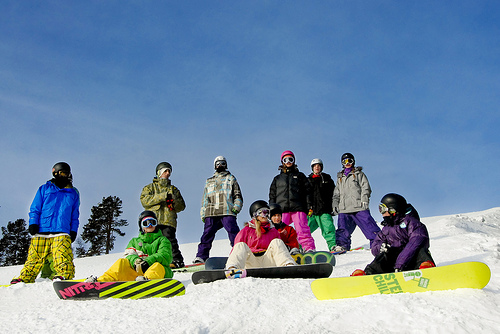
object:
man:
[10, 162, 80, 284]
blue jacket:
[28, 181, 80, 234]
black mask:
[52, 162, 72, 181]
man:
[85, 210, 173, 282]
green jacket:
[123, 229, 174, 279]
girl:
[224, 200, 298, 271]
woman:
[271, 151, 321, 254]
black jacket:
[269, 168, 316, 212]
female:
[330, 153, 381, 254]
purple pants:
[335, 209, 381, 251]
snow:
[198, 300, 282, 322]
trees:
[0, 195, 129, 266]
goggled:
[253, 208, 271, 218]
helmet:
[281, 149, 295, 161]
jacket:
[371, 214, 429, 268]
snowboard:
[311, 261, 491, 301]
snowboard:
[53, 278, 186, 301]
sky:
[0, 0, 499, 268]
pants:
[282, 211, 316, 253]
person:
[85, 210, 174, 282]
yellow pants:
[17, 233, 75, 283]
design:
[373, 273, 403, 294]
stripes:
[98, 279, 186, 300]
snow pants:
[224, 238, 298, 270]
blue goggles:
[282, 157, 294, 163]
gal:
[350, 193, 436, 277]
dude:
[298, 158, 336, 252]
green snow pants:
[298, 213, 336, 251]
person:
[269, 204, 299, 254]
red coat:
[278, 225, 299, 249]